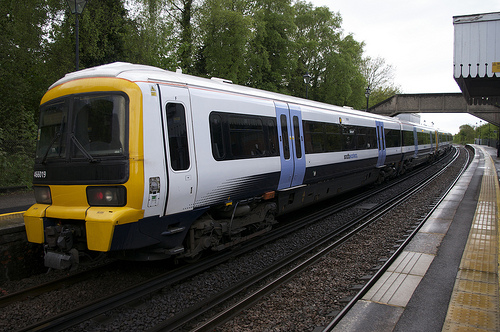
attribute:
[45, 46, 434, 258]
train — yellow, long, large, white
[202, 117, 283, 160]
windows — dark, left window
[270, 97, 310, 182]
doors — purple, blue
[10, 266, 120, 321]
tracks — metal, long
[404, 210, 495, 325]
platform — cement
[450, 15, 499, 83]
awning — wood, white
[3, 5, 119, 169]
trees — green, tall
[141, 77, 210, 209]
door — white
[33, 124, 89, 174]
wipers — up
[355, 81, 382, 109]
light — old fashion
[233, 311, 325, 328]
gravel — brown, black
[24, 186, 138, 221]
headlights — off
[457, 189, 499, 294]
line — yellow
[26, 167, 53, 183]
number — white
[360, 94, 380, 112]
pole — metal